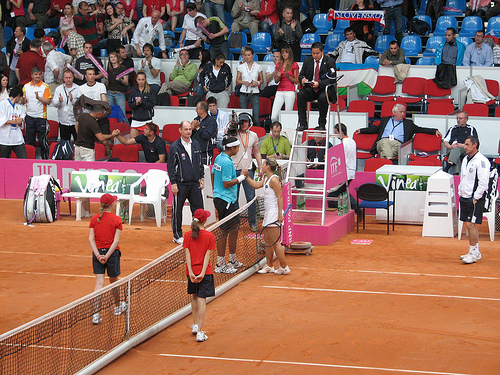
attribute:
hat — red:
[185, 210, 207, 225]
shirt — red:
[182, 213, 218, 277]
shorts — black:
[177, 269, 217, 298]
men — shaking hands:
[73, 103, 178, 172]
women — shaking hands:
[216, 142, 300, 290]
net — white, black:
[25, 256, 194, 374]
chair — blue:
[353, 173, 398, 232]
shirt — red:
[88, 208, 126, 259]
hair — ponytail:
[169, 206, 219, 234]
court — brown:
[137, 256, 490, 370]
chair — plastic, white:
[131, 171, 181, 231]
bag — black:
[20, 180, 60, 229]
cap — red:
[97, 162, 121, 207]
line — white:
[297, 254, 468, 307]